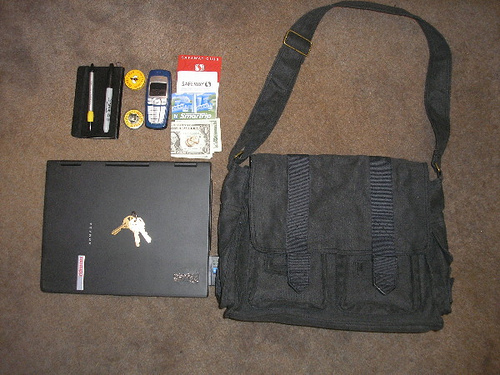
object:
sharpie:
[101, 62, 115, 134]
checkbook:
[69, 62, 125, 140]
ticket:
[174, 53, 222, 84]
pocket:
[247, 249, 329, 312]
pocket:
[332, 250, 423, 317]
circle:
[123, 69, 148, 90]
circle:
[121, 108, 145, 131]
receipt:
[174, 69, 219, 95]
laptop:
[37, 158, 215, 299]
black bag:
[213, 1, 461, 335]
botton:
[153, 97, 162, 106]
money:
[165, 115, 226, 160]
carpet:
[0, 0, 499, 374]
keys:
[108, 213, 136, 236]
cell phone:
[142, 69, 170, 129]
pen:
[85, 61, 96, 133]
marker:
[100, 61, 118, 137]